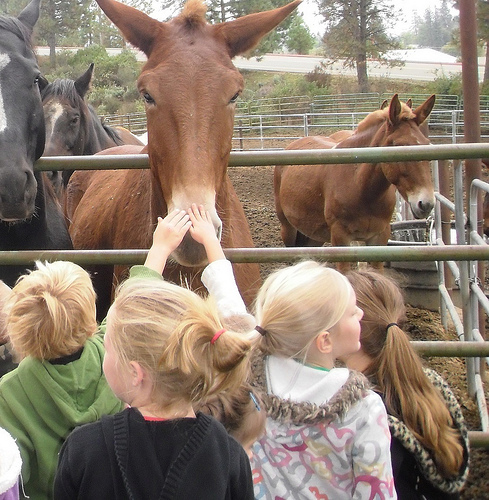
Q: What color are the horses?
A: Brown, black, and white.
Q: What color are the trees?
A: Brown and green.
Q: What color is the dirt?
A: Brown.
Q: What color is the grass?
A: Green.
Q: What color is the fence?
A: Gray.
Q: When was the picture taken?
A: Daytime.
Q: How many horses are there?
A: Four.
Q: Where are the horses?
A: On the dirt.